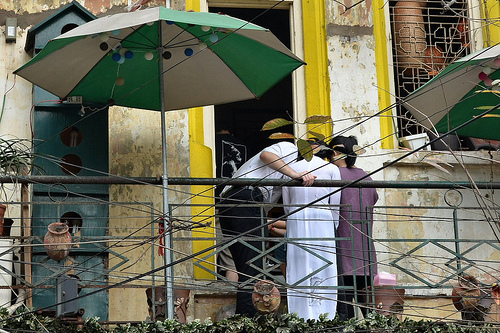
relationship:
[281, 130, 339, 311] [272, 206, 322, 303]
person wearing dress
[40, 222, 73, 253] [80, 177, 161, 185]
pot on railing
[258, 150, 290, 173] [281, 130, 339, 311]
arm of person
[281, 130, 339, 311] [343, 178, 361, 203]
person wearing purple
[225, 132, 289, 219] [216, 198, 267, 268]
man wearing slacks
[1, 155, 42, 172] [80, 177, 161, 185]
plants are growing around railing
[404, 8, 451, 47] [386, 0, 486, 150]
grill on window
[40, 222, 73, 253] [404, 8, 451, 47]
pot on grill